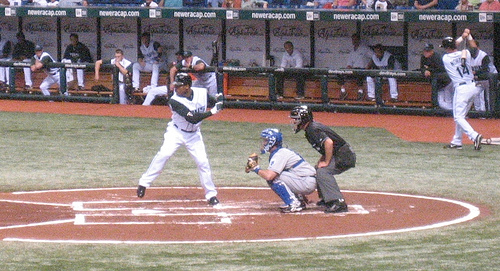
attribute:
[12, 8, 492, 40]
ledge — green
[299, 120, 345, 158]
shirt — black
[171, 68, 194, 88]
hat — black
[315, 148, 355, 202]
pants — gray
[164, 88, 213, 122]
top — black, white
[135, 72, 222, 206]
batter — left handed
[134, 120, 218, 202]
pants — white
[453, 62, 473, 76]
number — black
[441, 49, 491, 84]
top — white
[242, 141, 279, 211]
mit — brown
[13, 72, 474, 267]
field — green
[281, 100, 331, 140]
helmet — Black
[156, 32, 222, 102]
helmet — Black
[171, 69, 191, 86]
safety helmet — black, sporty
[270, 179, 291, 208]
safety pad — blue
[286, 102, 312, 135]
safety gear — black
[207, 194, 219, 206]
footwear — black, athletic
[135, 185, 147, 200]
footwear — black, athletic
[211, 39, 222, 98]
bat — black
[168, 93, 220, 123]
sleeves — black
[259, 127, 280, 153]
helmet — blue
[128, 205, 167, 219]
baseball plate — white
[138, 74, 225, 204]
player — baseball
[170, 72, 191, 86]
helmet — black 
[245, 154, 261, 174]
glove — brown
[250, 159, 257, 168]
hand — his, catcher's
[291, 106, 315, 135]
hemet — black